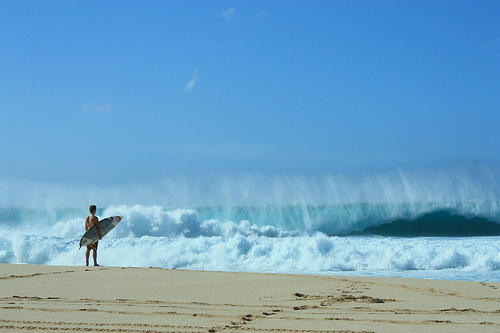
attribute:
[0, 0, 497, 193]
sky — clear , blue 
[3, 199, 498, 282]
water — white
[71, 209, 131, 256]
surfboard — gray and white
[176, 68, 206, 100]
clouds — small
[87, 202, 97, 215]
head — man's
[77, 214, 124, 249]
surfboard — large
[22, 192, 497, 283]
waves — white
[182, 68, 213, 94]
cloud — white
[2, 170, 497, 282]
water — Big splash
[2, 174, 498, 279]
ocean — vast expanse 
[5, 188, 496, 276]
waves — big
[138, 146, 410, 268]
wave — ocean's, of light spray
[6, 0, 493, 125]
skies — clear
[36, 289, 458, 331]
tracks — many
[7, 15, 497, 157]
sky —  clear ,  sunny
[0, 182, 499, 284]
wave — crashing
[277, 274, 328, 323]
prints — foot